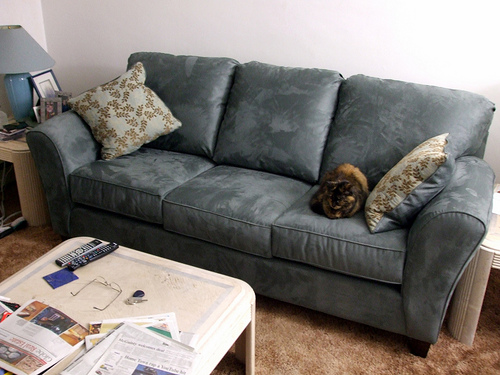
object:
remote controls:
[55, 238, 119, 271]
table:
[0, 92, 73, 232]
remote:
[56, 240, 120, 272]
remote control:
[55, 239, 103, 267]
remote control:
[66, 242, 119, 271]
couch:
[27, 53, 500, 362]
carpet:
[1, 222, 500, 374]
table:
[0, 237, 258, 374]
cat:
[310, 162, 370, 219]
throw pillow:
[365, 132, 455, 233]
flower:
[52, 89, 72, 104]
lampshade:
[0, 25, 55, 73]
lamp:
[4, 73, 36, 125]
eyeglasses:
[71, 275, 122, 312]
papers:
[0, 293, 198, 374]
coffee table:
[0, 235, 259, 374]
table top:
[0, 235, 258, 374]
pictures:
[29, 69, 70, 124]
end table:
[2, 104, 58, 229]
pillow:
[66, 62, 183, 162]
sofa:
[28, 52, 500, 361]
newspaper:
[0, 299, 196, 374]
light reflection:
[396, 1, 498, 93]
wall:
[0, 0, 499, 183]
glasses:
[71, 275, 122, 311]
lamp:
[0, 25, 56, 130]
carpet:
[261, 305, 434, 373]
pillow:
[365, 132, 455, 233]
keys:
[127, 290, 148, 306]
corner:
[0, 0, 73, 215]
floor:
[0, 218, 499, 375]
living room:
[0, 0, 499, 374]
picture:
[41, 97, 62, 124]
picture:
[28, 68, 63, 99]